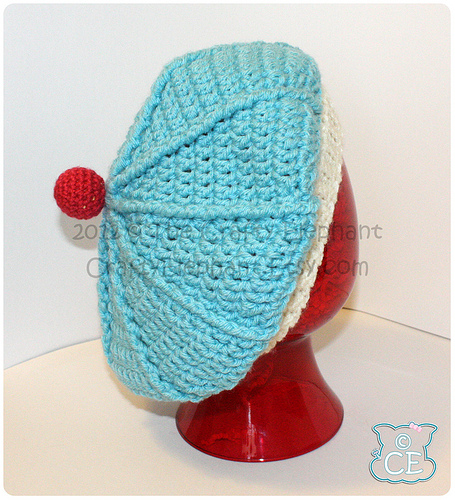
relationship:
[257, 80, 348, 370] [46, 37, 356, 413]
white on hat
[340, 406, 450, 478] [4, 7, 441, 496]
logo on photo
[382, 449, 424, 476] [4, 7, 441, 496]
ce written on photo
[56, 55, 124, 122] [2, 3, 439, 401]
wall in background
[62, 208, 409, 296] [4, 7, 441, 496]
watermark across photo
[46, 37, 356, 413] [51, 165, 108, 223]
hat has ball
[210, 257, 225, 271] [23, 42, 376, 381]
hole in hat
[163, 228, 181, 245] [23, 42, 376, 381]
hole in hat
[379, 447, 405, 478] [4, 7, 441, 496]
letter in photo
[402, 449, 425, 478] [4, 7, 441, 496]
letter in photo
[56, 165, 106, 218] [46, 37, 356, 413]
ball on hat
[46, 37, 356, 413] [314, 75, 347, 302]
hat has trim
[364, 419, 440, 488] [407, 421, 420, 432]
logo has bow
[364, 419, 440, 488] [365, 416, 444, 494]
logo in cecopyright